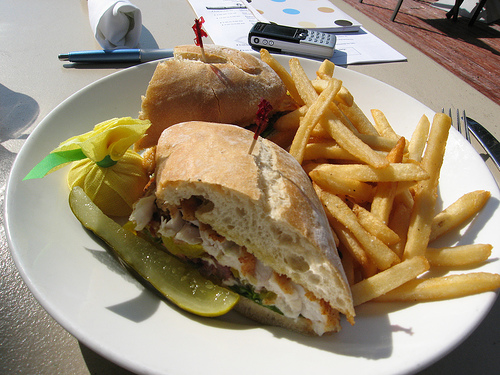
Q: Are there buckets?
A: No, there are no buckets.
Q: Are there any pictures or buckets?
A: No, there are no buckets or pictures.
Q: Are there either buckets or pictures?
A: No, there are no buckets or pictures.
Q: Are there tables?
A: Yes, there is a table.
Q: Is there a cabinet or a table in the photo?
A: Yes, there is a table.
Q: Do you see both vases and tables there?
A: No, there is a table but no vases.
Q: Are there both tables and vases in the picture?
A: No, there is a table but no vases.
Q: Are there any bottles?
A: No, there are no bottles.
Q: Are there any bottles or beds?
A: No, there are no bottles or beds.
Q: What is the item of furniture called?
A: The piece of furniture is a table.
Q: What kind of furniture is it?
A: The piece of furniture is a table.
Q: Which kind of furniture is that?
A: That is a table.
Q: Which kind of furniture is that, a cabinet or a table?
A: That is a table.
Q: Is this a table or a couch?
A: This is a table.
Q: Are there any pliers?
A: No, there are no pliers.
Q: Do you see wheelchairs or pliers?
A: No, there are no pliers or wheelchairs.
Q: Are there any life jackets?
A: No, there are no life jackets.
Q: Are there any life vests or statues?
A: No, there are no life vests or statues.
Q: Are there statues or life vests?
A: No, there are no life vests or statues.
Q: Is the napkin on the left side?
A: Yes, the napkin is on the left of the image.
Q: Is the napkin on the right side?
A: No, the napkin is on the left of the image.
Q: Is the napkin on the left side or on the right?
A: The napkin is on the left of the image.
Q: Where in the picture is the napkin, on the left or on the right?
A: The napkin is on the left of the image.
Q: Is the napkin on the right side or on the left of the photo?
A: The napkin is on the left of the image.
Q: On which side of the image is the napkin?
A: The napkin is on the left of the image.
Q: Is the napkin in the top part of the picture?
A: Yes, the napkin is in the top of the image.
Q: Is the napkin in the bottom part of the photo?
A: No, the napkin is in the top of the image.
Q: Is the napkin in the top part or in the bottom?
A: The napkin is in the top of the image.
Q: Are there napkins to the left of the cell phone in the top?
A: Yes, there is a napkin to the left of the cellphone.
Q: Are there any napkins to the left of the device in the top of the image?
A: Yes, there is a napkin to the left of the cellphone.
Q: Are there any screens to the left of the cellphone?
A: No, there is a napkin to the left of the cellphone.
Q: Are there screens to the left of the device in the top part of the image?
A: No, there is a napkin to the left of the cellphone.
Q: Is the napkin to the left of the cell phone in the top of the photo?
A: Yes, the napkin is to the left of the cell phone.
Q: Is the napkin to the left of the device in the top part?
A: Yes, the napkin is to the left of the cell phone.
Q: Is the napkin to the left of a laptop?
A: No, the napkin is to the left of the cell phone.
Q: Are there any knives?
A: Yes, there is a knife.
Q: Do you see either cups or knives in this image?
A: Yes, there is a knife.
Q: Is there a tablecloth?
A: No, there are no tablecloths.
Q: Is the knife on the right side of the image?
A: Yes, the knife is on the right of the image.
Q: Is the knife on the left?
A: No, the knife is on the right of the image.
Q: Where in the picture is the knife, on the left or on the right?
A: The knife is on the right of the image.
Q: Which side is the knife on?
A: The knife is on the right of the image.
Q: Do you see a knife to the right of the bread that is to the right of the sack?
A: Yes, there is a knife to the right of the bread.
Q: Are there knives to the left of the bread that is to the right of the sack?
A: No, the knife is to the right of the bread.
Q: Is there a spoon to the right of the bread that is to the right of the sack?
A: No, there is a knife to the right of the bread.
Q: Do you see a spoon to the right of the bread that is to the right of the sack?
A: No, there is a knife to the right of the bread.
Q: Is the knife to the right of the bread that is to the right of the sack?
A: Yes, the knife is to the right of the bread.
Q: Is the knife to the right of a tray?
A: No, the knife is to the right of the bread.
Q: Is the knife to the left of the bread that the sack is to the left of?
A: No, the knife is to the right of the bread.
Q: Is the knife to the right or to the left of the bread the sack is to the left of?
A: The knife is to the right of the bread.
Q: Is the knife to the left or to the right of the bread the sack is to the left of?
A: The knife is to the right of the bread.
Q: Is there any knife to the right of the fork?
A: Yes, there is a knife to the right of the fork.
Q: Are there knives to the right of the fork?
A: Yes, there is a knife to the right of the fork.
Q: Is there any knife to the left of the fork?
A: No, the knife is to the right of the fork.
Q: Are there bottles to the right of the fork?
A: No, there is a knife to the right of the fork.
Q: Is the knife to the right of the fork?
A: Yes, the knife is to the right of the fork.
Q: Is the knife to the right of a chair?
A: No, the knife is to the right of the fork.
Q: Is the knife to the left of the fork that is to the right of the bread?
A: No, the knife is to the right of the fork.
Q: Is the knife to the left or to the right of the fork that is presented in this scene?
A: The knife is to the right of the fork.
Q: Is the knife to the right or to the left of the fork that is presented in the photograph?
A: The knife is to the right of the fork.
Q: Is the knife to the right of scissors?
A: No, the knife is to the right of the fries.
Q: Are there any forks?
A: Yes, there is a fork.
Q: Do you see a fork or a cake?
A: Yes, there is a fork.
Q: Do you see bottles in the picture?
A: No, there are no bottles.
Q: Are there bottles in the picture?
A: No, there are no bottles.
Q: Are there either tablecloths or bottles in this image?
A: No, there are no bottles or tablecloths.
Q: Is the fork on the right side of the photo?
A: Yes, the fork is on the right of the image.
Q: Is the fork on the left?
A: No, the fork is on the right of the image.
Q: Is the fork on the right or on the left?
A: The fork is on the right of the image.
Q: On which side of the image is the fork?
A: The fork is on the right of the image.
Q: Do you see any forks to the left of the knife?
A: Yes, there is a fork to the left of the knife.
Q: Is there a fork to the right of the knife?
A: No, the fork is to the left of the knife.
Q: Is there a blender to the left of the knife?
A: No, there is a fork to the left of the knife.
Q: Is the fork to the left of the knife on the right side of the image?
A: Yes, the fork is to the left of the knife.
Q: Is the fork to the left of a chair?
A: No, the fork is to the left of the knife.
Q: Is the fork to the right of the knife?
A: No, the fork is to the left of the knife.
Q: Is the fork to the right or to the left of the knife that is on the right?
A: The fork is to the left of the knife.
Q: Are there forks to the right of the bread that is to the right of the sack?
A: Yes, there is a fork to the right of the bread.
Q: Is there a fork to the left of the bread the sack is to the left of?
A: No, the fork is to the right of the bread.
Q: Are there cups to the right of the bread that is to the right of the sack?
A: No, there is a fork to the right of the bread.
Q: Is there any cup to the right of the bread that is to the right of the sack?
A: No, there is a fork to the right of the bread.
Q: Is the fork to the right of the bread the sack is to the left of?
A: Yes, the fork is to the right of the bread.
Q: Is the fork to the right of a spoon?
A: No, the fork is to the right of the bread.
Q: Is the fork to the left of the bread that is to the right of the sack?
A: No, the fork is to the right of the bread.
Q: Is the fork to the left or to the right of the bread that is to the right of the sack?
A: The fork is to the right of the bread.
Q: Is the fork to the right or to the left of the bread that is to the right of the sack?
A: The fork is to the right of the bread.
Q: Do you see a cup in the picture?
A: No, there are no cups.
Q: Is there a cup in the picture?
A: No, there are no cups.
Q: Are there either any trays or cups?
A: No, there are no cups or trays.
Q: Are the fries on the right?
A: Yes, the fries are on the right of the image.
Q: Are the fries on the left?
A: No, the fries are on the right of the image.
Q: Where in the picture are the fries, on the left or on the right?
A: The fries are on the right of the image.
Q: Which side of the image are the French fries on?
A: The French fries are on the right of the image.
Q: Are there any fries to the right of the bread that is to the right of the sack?
A: Yes, there are fries to the right of the bread.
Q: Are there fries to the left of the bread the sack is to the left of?
A: No, the fries are to the right of the bread.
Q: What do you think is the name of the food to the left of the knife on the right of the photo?
A: The food is fries.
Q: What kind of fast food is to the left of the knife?
A: The food is fries.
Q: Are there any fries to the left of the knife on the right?
A: Yes, there are fries to the left of the knife.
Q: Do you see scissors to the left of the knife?
A: No, there are fries to the left of the knife.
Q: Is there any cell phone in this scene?
A: Yes, there is a cell phone.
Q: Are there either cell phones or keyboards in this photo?
A: Yes, there is a cell phone.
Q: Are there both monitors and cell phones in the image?
A: No, there is a cell phone but no monitors.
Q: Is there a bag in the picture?
A: No, there are no bags.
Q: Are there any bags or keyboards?
A: No, there are no bags or keyboards.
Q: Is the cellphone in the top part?
A: Yes, the cellphone is in the top of the image.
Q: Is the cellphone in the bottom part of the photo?
A: No, the cellphone is in the top of the image.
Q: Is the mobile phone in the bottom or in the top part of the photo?
A: The mobile phone is in the top of the image.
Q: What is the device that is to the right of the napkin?
A: The device is a cell phone.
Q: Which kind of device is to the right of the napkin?
A: The device is a cell phone.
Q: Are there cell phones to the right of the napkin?
A: Yes, there is a cell phone to the right of the napkin.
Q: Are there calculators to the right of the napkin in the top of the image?
A: No, there is a cell phone to the right of the napkin.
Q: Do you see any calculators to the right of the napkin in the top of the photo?
A: No, there is a cell phone to the right of the napkin.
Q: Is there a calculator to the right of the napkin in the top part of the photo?
A: No, there is a cell phone to the right of the napkin.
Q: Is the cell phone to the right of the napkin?
A: Yes, the cell phone is to the right of the napkin.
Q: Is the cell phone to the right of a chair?
A: No, the cell phone is to the right of the napkin.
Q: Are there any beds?
A: No, there are no beds.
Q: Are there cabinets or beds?
A: No, there are no beds or cabinets.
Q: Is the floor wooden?
A: Yes, the floor is wooden.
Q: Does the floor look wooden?
A: Yes, the floor is wooden.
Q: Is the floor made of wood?
A: Yes, the floor is made of wood.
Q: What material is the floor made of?
A: The floor is made of wood.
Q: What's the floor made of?
A: The floor is made of wood.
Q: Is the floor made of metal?
A: No, the floor is made of wood.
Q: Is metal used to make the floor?
A: No, the floor is made of wood.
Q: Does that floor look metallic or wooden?
A: The floor is wooden.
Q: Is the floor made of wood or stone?
A: The floor is made of wood.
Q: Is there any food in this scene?
A: Yes, there is food.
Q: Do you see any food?
A: Yes, there is food.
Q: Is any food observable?
A: Yes, there is food.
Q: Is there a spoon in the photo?
A: No, there are no spoons.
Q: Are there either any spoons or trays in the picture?
A: No, there are no spoons or trays.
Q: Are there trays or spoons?
A: No, there are no spoons or trays.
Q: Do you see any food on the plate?
A: Yes, there is food on the plate.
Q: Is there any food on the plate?
A: Yes, there is food on the plate.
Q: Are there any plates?
A: Yes, there is a plate.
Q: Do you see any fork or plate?
A: Yes, there is a plate.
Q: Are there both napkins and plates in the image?
A: Yes, there are both a plate and a napkin.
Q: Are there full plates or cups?
A: Yes, there is a full plate.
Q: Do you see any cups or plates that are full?
A: Yes, the plate is full.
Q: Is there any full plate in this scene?
A: Yes, there is a full plate.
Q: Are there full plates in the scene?
A: Yes, there is a full plate.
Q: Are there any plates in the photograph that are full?
A: Yes, there is a plate that is full.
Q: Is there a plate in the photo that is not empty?
A: Yes, there is an full plate.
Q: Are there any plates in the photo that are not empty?
A: Yes, there is an full plate.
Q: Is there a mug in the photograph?
A: No, there are no mugs.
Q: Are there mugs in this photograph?
A: No, there are no mugs.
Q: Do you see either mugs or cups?
A: No, there are no mugs or cups.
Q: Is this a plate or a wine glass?
A: This is a plate.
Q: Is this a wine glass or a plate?
A: This is a plate.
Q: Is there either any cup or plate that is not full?
A: No, there is a plate but it is full.